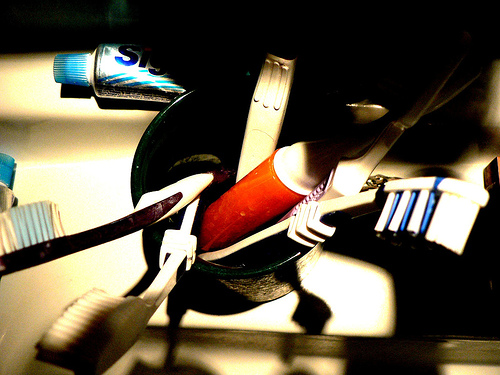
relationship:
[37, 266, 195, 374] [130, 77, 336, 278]
white toothbrush in green cup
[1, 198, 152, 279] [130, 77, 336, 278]
brown toothbrush in green cup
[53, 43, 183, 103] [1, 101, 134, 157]
toothpaste at sink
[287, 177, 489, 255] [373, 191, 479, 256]
toothbrush with blue and white bristles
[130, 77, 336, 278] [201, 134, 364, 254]
green cup with an orange water pik brush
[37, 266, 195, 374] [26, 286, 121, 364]
toothbrush with white bristles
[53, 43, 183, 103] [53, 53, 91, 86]
toothpaste has a blue cap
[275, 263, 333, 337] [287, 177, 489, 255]
shadows formed of toothbrushes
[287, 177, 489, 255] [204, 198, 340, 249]
toothbrush grips on handle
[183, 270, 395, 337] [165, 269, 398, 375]
light formed a shadow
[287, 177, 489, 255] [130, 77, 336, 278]
toothbrush in green cup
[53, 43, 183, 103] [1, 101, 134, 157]
toothpaste on counter sink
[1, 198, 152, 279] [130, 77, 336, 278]
toothbrushes in green cup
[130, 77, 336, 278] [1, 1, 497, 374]
green cup holding toothbrushes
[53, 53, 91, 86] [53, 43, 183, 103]
screw cap to toothpaste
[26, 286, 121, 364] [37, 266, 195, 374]
white bristles on a white toothbrush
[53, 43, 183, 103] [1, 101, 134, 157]
toothpaste on sink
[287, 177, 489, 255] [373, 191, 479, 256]
toothbrush with white and blue bristles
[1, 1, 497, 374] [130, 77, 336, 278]
toothbrushes in a green cup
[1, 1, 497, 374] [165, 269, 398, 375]
room light made a shadow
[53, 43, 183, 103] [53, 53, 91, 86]
toothpaste has a screw on cap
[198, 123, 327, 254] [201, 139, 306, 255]
electric toothbrush with an orange handle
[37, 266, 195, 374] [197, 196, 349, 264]
toothbrush with a white handle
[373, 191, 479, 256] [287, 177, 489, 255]
bristles are blue and white on the toothbrush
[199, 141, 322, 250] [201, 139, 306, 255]
toothbrush has a red grip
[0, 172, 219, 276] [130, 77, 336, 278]
toothbrushes are in a green cup container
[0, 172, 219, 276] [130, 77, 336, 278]
toothbrushes are all in green cup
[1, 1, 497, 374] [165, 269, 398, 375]
lighting has made shadows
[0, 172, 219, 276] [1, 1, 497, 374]
toothbrushes are many colors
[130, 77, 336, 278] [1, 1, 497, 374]
green cup holding many toothbrushes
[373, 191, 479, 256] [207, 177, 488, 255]
bristles are blue and white on the toothbrush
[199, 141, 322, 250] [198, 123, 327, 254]
orange handle of electric toothbrush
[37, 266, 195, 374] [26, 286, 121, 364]
toothbrush has white bristles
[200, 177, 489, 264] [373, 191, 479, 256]
toothbrush with white and blue bristles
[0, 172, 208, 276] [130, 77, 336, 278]
purple toothbrush in cup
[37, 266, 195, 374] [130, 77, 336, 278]
many toothbrushes in green mug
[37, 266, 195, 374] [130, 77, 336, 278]
white toothbrush in green mug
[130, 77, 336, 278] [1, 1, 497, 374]
green mug holds many toothbrushes